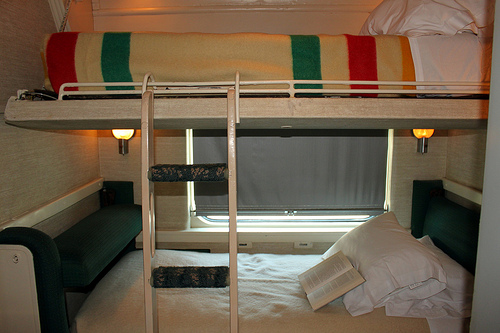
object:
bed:
[3, 71, 494, 129]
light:
[410, 128, 435, 155]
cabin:
[0, 0, 500, 333]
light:
[110, 129, 134, 156]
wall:
[0, 0, 102, 230]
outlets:
[237, 239, 252, 249]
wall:
[100, 13, 450, 255]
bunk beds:
[0, 71, 500, 333]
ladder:
[139, 71, 242, 333]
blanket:
[40, 29, 494, 99]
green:
[308, 101, 361, 116]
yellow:
[206, 57, 261, 73]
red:
[353, 58, 373, 78]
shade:
[217, 131, 386, 211]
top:
[320, 211, 476, 320]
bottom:
[435, 270, 471, 333]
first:
[150, 266, 229, 288]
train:
[0, 0, 500, 333]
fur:
[150, 265, 230, 288]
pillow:
[320, 211, 448, 318]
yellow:
[98, 128, 141, 138]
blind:
[186, 127, 394, 227]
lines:
[56, 81, 236, 100]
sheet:
[41, 29, 493, 98]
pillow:
[384, 235, 474, 319]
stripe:
[288, 35, 322, 99]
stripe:
[100, 31, 135, 91]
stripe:
[343, 33, 380, 97]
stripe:
[45, 32, 80, 93]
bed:
[0, 177, 483, 333]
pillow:
[357, 0, 492, 39]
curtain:
[192, 129, 388, 216]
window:
[186, 127, 393, 228]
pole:
[225, 86, 239, 333]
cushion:
[52, 203, 142, 287]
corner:
[333, 263, 367, 295]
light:
[163, 238, 340, 300]